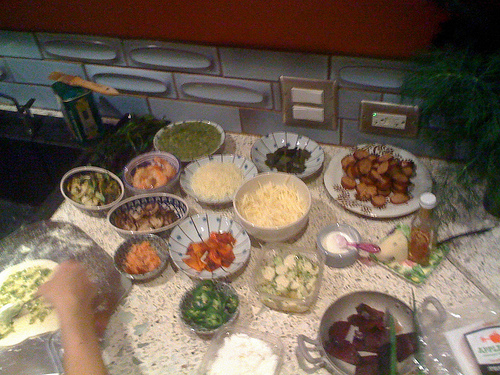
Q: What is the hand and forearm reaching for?
A: A plate that is on the table.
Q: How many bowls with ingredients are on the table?
A: 15.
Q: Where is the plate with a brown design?
A: On the back of the table.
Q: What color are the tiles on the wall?
A: Blue.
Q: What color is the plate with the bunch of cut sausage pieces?
A: White with brown design.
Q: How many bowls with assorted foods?
A: 14.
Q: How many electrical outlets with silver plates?
A: 2.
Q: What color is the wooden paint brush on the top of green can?
A: Tan.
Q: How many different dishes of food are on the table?
A: Fourteen.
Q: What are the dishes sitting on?
A: Table.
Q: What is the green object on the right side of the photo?
A: Plant.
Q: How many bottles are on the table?
A: One.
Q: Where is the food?
A: On the table.